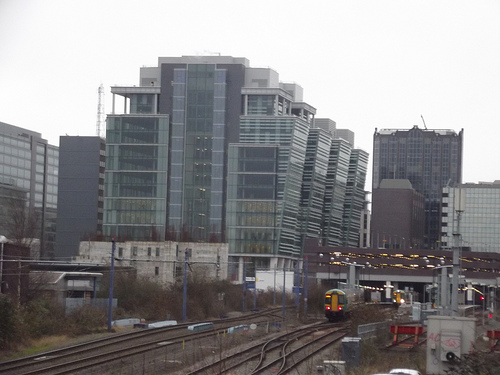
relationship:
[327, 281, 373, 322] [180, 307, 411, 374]
train on tracks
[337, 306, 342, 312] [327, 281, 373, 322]
headlights on train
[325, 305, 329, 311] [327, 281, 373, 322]
headlights on train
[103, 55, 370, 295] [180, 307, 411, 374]
building near tracks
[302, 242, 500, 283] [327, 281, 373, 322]
garage near train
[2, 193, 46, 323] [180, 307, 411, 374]
trees near tracks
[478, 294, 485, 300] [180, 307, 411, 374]
light near tracks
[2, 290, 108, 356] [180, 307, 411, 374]
bushes beside tracks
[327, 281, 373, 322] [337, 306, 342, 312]
train with headlights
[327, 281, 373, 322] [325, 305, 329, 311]
train with headlights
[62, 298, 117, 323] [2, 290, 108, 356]
trailer in bushes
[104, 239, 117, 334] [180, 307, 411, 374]
post alongside tracks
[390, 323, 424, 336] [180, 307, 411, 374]
sign near tracks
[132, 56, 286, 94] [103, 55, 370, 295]
tower on building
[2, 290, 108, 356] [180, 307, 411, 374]
bushes next to tracks